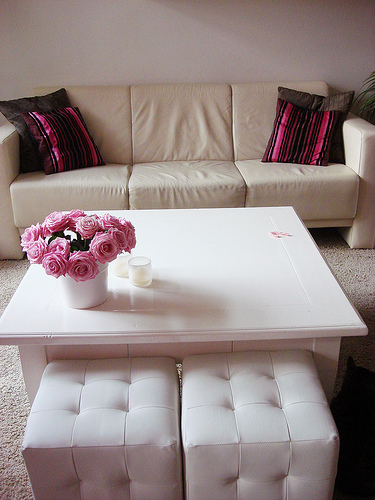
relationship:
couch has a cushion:
[3, 74, 375, 253] [128, 152, 248, 210]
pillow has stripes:
[266, 96, 346, 162] [279, 120, 312, 145]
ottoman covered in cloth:
[180, 348, 344, 499] [209, 418, 277, 441]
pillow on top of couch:
[266, 96, 346, 162] [3, 74, 375, 253]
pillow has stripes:
[28, 104, 103, 177] [279, 120, 312, 145]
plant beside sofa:
[354, 68, 375, 126] [3, 74, 375, 253]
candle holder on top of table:
[128, 254, 153, 292] [1, 203, 372, 358]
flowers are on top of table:
[20, 211, 131, 284] [1, 203, 372, 358]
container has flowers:
[60, 257, 108, 310] [20, 211, 131, 284]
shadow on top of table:
[106, 284, 212, 327] [1, 203, 372, 358]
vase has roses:
[60, 257, 108, 310] [20, 211, 131, 284]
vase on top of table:
[60, 257, 108, 310] [1, 203, 372, 358]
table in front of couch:
[1, 203, 372, 358] [3, 74, 375, 253]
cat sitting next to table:
[334, 355, 374, 483] [1, 203, 372, 358]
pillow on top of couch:
[0, 85, 103, 176] [3, 74, 375, 253]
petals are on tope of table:
[268, 230, 300, 238] [1, 203, 372, 358]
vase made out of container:
[60, 257, 108, 310] [60, 257, 108, 310]